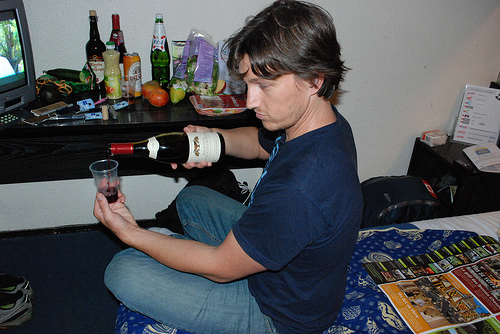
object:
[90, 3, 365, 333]
man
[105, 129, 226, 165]
bottle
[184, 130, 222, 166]
label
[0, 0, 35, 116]
tv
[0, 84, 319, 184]
table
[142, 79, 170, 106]
apples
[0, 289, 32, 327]
shoes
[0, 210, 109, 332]
floor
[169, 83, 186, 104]
pear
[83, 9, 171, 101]
bottles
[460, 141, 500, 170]
brochure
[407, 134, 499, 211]
nightstand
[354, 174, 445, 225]
backpack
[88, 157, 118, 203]
cup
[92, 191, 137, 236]
hand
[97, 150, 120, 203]
wine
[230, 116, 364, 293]
shirt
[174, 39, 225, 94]
salad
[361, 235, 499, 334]
paper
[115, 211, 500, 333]
bed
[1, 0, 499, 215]
wall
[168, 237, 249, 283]
elbow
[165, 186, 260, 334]
lap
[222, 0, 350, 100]
hair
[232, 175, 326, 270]
sleeve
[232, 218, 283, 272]
edge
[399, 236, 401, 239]
part